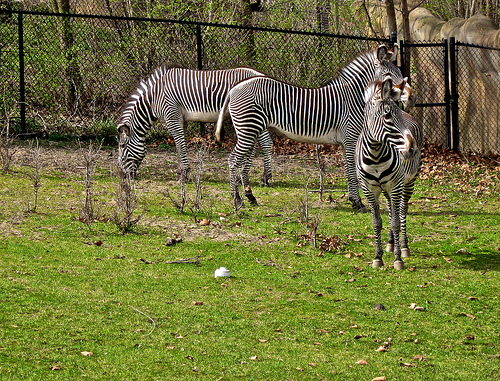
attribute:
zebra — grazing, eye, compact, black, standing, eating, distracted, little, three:
[355, 81, 424, 269]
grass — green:
[4, 172, 496, 379]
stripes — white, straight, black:
[244, 90, 356, 149]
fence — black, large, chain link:
[3, 8, 498, 158]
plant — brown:
[7, 126, 217, 256]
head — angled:
[363, 73, 432, 168]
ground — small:
[3, 126, 499, 380]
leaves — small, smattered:
[6, 6, 419, 151]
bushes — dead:
[5, 124, 337, 266]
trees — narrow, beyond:
[47, 2, 427, 129]